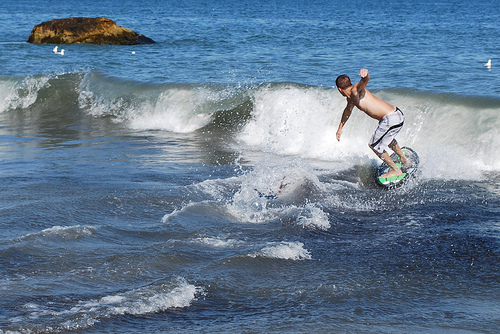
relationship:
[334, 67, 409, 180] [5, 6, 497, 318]
boy surfing in ocean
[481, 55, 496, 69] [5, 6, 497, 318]
bird in ocean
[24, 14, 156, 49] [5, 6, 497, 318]
formation inside of ocean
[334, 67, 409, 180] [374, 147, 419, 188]
boy on top of board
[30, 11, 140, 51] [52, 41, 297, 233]
rock jutting out of water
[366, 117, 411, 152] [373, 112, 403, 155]
stripe attached to trunks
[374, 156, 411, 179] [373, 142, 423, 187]
feet are on top of surfboard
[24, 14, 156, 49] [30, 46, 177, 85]
formation inside of water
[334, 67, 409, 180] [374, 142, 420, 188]
boy on top of board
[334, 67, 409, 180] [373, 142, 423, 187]
boy on top of surfboard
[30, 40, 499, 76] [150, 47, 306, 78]
birds are on top of water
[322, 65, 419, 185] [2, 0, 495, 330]
boy plays in water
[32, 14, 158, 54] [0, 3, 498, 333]
formation sticks out of ocean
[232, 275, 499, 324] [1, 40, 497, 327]
surface of water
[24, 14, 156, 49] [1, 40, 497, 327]
formation in water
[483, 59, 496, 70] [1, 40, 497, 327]
bird floating on water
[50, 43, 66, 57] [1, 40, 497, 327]
birds floating on water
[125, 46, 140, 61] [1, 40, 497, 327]
seagull floating on water